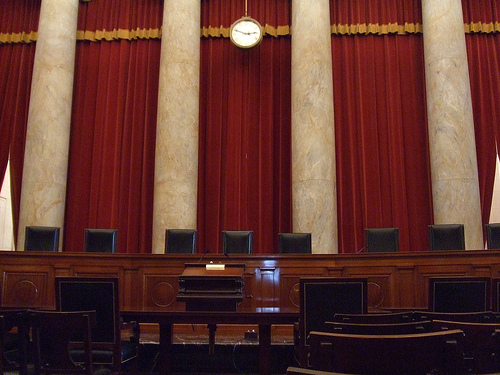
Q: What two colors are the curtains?
A: Red and gold.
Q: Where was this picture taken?
A: In a court.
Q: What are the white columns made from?
A: Marble.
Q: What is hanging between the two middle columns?
A: A clock.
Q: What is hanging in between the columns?
A: Curtains.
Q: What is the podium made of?
A: Wood.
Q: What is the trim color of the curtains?
A: Gold.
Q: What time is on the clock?
A: 2:50.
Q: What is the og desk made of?
A: Wood.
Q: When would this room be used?
A: For important decisions to be made.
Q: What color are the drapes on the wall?
A: Red.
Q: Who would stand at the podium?
A: The speaker.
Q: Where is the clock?
A: In the center along the top.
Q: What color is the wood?
A: Brown.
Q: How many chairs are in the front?
A: Eight.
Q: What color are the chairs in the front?
A: Black.